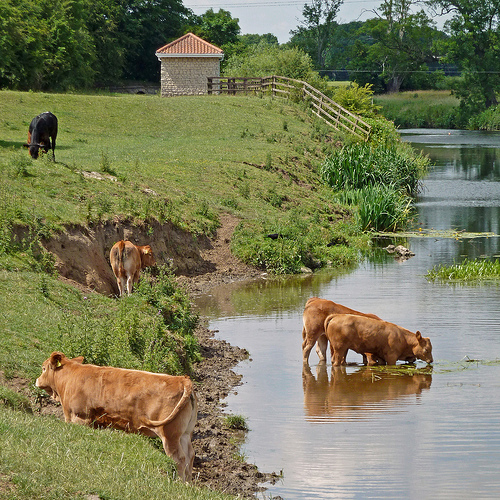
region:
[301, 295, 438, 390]
cows drinking in the water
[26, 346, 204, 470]
cow standing near the water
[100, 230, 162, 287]
cow facing the dirt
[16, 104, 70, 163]
animal on the grass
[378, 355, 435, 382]
grass in the water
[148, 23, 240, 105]
building on the terrain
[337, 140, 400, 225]
plants near the water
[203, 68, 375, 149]
A wooden fence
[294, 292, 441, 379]
Two brown cows standing in water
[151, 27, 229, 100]
A brick building with a red roof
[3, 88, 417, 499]
A green, grassy hill beside a river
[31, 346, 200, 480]
A light-brown cow walking away from the water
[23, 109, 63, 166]
A black cow grazing on the grass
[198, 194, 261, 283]
A path leading up the hill from the water's edge.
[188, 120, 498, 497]
A calm, peaceful river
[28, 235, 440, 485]
Group of four brown cows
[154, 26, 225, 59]
A red roof on a brick building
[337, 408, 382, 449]
Small patch of the pond water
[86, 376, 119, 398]
Brown skin of the cow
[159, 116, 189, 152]
Small patch of green grass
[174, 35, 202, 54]
Orange roof on the small house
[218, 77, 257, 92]
Small section of the brown wooden fence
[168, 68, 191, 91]
Brown brick wall of the small house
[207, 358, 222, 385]
Small patch of the dirt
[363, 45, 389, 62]
Green leaves on the tree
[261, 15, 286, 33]
Small patch of the light blue sky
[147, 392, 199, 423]
Brown tail of the cow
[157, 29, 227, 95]
Small stone building.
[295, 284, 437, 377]
Two cows standing in the water.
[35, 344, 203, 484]
Cow standing on land.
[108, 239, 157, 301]
Cow standing looking towards water.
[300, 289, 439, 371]
Two brown cows standing together.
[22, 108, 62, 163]
Black cow grazing.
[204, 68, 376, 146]
Wooden fence.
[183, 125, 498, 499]
Stream.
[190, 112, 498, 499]
Stream with two cows drinking in it.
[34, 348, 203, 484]
Brown cow flicking its tail.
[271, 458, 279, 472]
edge of a hill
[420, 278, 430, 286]
part of a bush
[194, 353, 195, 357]
edge of a shore